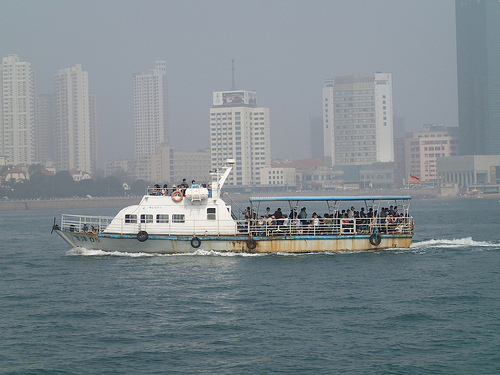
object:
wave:
[63, 237, 497, 259]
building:
[401, 123, 459, 185]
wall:
[421, 129, 458, 169]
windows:
[124, 212, 186, 225]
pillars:
[80, 12, 498, 205]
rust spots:
[233, 240, 370, 251]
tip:
[50, 216, 62, 234]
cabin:
[103, 195, 238, 234]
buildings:
[1, 0, 497, 188]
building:
[0, 52, 47, 166]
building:
[52, 61, 101, 177]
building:
[128, 58, 173, 185]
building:
[207, 55, 274, 187]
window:
[382, 94, 387, 126]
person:
[241, 206, 252, 230]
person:
[161, 183, 169, 196]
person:
[152, 183, 161, 195]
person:
[360, 207, 366, 229]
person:
[263, 207, 270, 220]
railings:
[60, 212, 413, 237]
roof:
[248, 195, 412, 202]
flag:
[408, 173, 420, 183]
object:
[182, 231, 253, 255]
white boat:
[103, 158, 236, 252]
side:
[222, 235, 415, 252]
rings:
[128, 230, 393, 250]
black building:
[453, 0, 500, 154]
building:
[319, 70, 399, 167]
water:
[0, 200, 499, 373]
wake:
[411, 234, 497, 253]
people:
[242, 205, 415, 233]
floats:
[69, 230, 268, 259]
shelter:
[243, 197, 411, 237]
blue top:
[248, 195, 412, 204]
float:
[171, 189, 183, 202]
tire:
[246, 239, 257, 249]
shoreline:
[0, 183, 441, 213]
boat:
[50, 159, 420, 257]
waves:
[65, 240, 124, 257]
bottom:
[233, 234, 414, 254]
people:
[151, 178, 215, 197]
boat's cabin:
[103, 158, 238, 236]